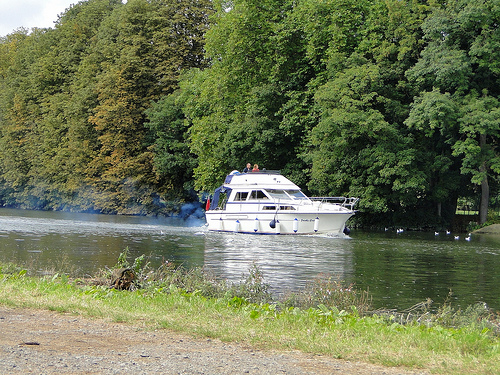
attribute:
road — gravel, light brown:
[0, 304, 395, 372]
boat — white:
[199, 172, 355, 240]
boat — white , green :
[202, 170, 358, 236]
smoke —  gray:
[147, 153, 284, 223]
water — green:
[118, 225, 413, 286]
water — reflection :
[247, 252, 421, 281]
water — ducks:
[368, 243, 451, 293]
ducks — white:
[392, 220, 476, 251]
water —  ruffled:
[369, 241, 452, 303]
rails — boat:
[215, 188, 315, 215]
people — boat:
[210, 156, 280, 226]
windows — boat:
[235, 186, 269, 205]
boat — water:
[199, 160, 371, 240]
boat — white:
[199, 155, 361, 244]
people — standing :
[200, 150, 264, 208]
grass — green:
[154, 296, 329, 353]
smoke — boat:
[114, 139, 243, 186]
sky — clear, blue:
[15, 8, 29, 22]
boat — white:
[221, 176, 337, 246]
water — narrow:
[174, 207, 304, 277]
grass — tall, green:
[132, 294, 220, 324]